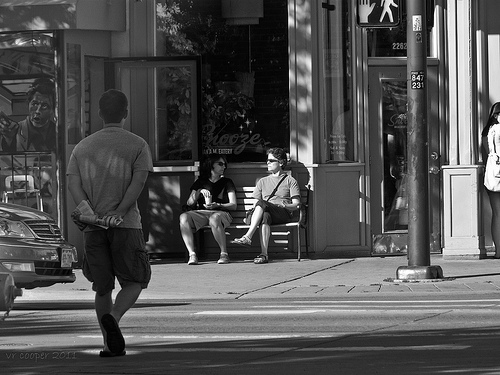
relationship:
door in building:
[357, 56, 462, 251] [271, 16, 470, 263]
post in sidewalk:
[394, 266, 444, 281] [0, 252, 500, 309]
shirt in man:
[67, 127, 153, 224] [64, 90, 155, 358]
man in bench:
[64, 90, 155, 358] [175, 176, 310, 258]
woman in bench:
[176, 150, 241, 267] [195, 182, 312, 263]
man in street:
[64, 93, 160, 357] [9, 299, 498, 371]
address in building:
[390, 41, 407, 50] [4, 2, 496, 269]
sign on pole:
[353, 0, 402, 30] [398, 0, 443, 280]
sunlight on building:
[276, 45, 326, 139] [129, 5, 410, 180]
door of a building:
[363, 31, 438, 251] [4, 2, 496, 269]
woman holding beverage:
[169, 149, 270, 271] [202, 196, 213, 203]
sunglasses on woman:
[260, 157, 286, 167] [233, 122, 326, 267]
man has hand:
[64, 90, 155, 358] [104, 210, 124, 230]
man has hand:
[64, 90, 155, 358] [78, 216, 103, 231]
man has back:
[64, 90, 155, 358] [72, 138, 143, 231]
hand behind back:
[104, 210, 124, 230] [72, 138, 143, 231]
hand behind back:
[78, 216, 103, 231] [72, 138, 143, 231]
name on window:
[154, 119, 268, 160] [193, 60, 296, 151]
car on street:
[0, 201, 76, 291] [14, 301, 480, 361]